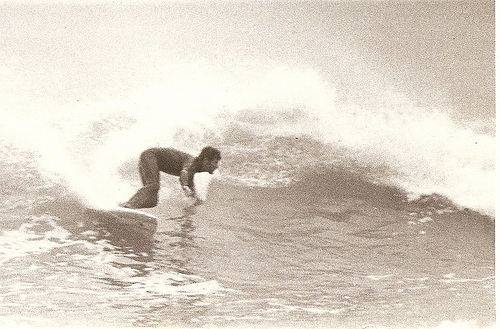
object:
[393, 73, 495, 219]
wave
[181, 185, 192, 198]
hand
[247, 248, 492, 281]
water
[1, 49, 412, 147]
water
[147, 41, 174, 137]
waves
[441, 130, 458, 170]
ground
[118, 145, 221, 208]
surfer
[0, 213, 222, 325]
foam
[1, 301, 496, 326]
water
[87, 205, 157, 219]
surfboard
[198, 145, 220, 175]
head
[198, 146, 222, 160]
hair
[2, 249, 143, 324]
wave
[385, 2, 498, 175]
spray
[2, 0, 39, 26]
waves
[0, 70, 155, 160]
foam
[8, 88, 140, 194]
wave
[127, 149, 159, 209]
legs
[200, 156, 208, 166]
ear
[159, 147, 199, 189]
shirt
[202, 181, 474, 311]
calm area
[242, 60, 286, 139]
wave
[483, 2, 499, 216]
water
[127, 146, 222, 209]
man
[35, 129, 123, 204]
water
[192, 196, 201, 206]
hand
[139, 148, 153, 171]
butt